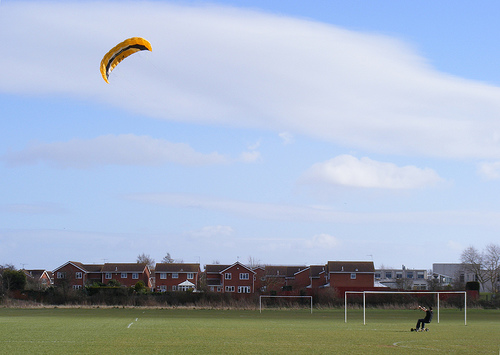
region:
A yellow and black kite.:
[97, 38, 153, 85]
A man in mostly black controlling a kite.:
[413, 304, 435, 331]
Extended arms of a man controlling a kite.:
[416, 303, 427, 313]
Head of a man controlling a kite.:
[426, 304, 433, 311]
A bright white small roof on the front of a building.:
[178, 277, 193, 288]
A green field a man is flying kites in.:
[1, 305, 498, 354]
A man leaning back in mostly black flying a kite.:
[414, 302, 434, 330]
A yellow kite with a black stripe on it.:
[98, 37, 153, 82]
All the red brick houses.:
[1, 260, 376, 304]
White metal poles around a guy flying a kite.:
[344, 289, 467, 326]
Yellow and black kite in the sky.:
[100, 38, 153, 84]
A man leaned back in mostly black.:
[414, 303, 434, 332]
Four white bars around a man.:
[342, 290, 467, 327]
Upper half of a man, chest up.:
[425, 304, 433, 322]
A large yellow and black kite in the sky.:
[100, 36, 158, 81]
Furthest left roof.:
[15, 268, 51, 288]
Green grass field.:
[2, 307, 497, 354]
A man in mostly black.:
[411, 303, 434, 335]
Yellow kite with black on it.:
[100, 35, 153, 82]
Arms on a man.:
[417, 303, 427, 314]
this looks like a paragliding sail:
[93, 24, 158, 89]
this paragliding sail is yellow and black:
[97, 33, 157, 85]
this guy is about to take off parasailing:
[404, 301, 436, 335]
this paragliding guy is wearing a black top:
[407, 303, 437, 332]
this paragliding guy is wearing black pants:
[408, 300, 439, 332]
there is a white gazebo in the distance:
[174, 277, 196, 294]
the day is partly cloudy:
[176, 98, 498, 238]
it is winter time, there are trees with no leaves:
[455, 237, 499, 313]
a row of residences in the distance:
[23, 252, 381, 304]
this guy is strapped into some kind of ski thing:
[405, 298, 439, 335]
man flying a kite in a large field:
[408, 302, 436, 334]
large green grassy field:
[0, 309, 499, 353]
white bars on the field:
[259, 289, 467, 324]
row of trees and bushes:
[3, 262, 499, 308]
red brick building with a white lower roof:
[153, 261, 198, 291]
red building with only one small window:
[326, 259, 378, 291]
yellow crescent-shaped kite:
[98, 36, 155, 81]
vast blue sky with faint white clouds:
[1, 0, 498, 271]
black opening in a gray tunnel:
[463, 280, 484, 293]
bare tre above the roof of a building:
[136, 253, 154, 269]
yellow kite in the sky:
[97, 19, 166, 88]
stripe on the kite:
[100, 37, 161, 79]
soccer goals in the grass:
[336, 279, 481, 345]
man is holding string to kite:
[399, 300, 450, 353]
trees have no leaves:
[462, 227, 496, 302]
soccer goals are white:
[338, 280, 484, 354]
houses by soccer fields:
[33, 256, 379, 301]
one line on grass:
[126, 312, 164, 339]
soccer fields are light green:
[148, 317, 308, 351]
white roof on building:
[170, 275, 198, 292]